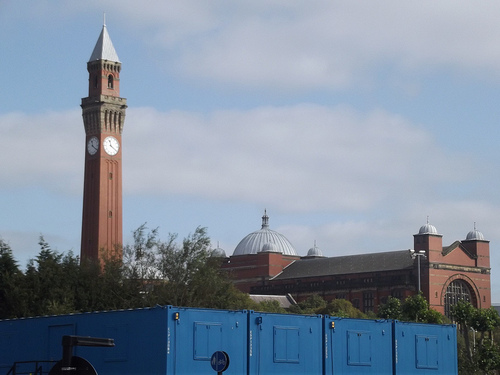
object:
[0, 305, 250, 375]
trailer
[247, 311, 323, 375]
trailer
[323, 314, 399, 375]
trailer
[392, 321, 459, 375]
trailer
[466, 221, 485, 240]
mound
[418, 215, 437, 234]
mound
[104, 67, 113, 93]
window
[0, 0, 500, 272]
cloud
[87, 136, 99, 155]
clock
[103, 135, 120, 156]
clock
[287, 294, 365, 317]
trees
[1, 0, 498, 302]
white clouds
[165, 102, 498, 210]
white louds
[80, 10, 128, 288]
clock tower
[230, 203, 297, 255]
round top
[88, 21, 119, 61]
pyramid shape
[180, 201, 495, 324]
building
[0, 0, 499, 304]
blue sky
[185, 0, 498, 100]
white clouds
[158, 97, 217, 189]
white clouds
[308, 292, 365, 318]
tree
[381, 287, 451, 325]
tree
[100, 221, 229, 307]
tree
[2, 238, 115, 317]
tree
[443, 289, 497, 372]
tree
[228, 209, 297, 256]
mound